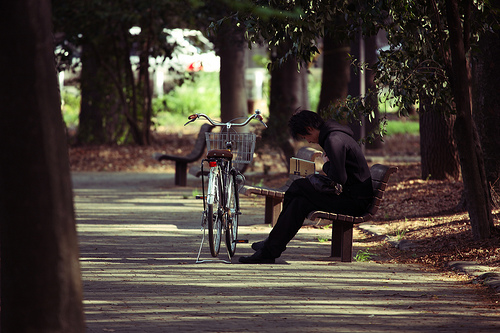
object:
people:
[181, 55, 212, 78]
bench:
[158, 115, 215, 192]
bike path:
[56, 180, 497, 333]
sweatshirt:
[317, 120, 377, 202]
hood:
[319, 115, 356, 135]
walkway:
[69, 159, 500, 333]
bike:
[178, 103, 265, 256]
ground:
[176, 97, 271, 291]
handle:
[176, 110, 267, 126]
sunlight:
[84, 216, 172, 257]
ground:
[79, 202, 186, 307]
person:
[237, 95, 372, 272]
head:
[287, 108, 319, 140]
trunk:
[324, 0, 360, 132]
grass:
[362, 87, 437, 127]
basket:
[203, 129, 258, 164]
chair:
[310, 163, 397, 262]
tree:
[438, 0, 498, 253]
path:
[54, 127, 302, 330]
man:
[271, 81, 377, 285]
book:
[287, 152, 319, 178]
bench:
[285, 152, 401, 268]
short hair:
[289, 111, 323, 126]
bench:
[237, 127, 406, 266]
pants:
[257, 177, 377, 263]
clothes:
[246, 135, 380, 261]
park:
[0, 3, 493, 331]